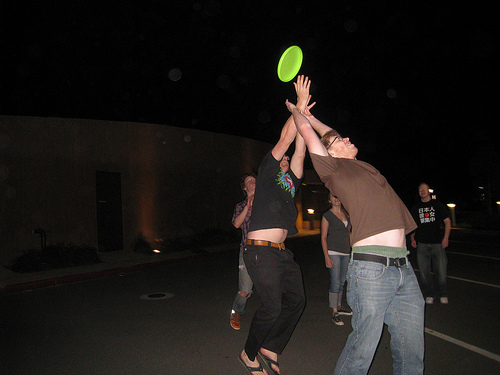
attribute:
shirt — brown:
[310, 156, 416, 243]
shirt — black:
[245, 153, 301, 231]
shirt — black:
[416, 199, 451, 242]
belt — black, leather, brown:
[351, 252, 409, 265]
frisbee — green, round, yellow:
[276, 44, 303, 81]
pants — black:
[243, 245, 306, 360]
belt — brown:
[245, 240, 290, 248]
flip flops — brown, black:
[236, 351, 283, 374]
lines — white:
[423, 246, 499, 362]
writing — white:
[417, 206, 435, 224]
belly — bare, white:
[354, 230, 408, 248]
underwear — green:
[353, 246, 407, 257]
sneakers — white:
[424, 293, 447, 304]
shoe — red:
[229, 312, 242, 328]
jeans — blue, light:
[334, 263, 424, 375]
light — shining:
[152, 250, 160, 255]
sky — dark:
[0, 0, 499, 120]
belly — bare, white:
[248, 228, 285, 242]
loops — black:
[249, 239, 275, 247]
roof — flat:
[1, 112, 280, 125]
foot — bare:
[241, 348, 262, 375]